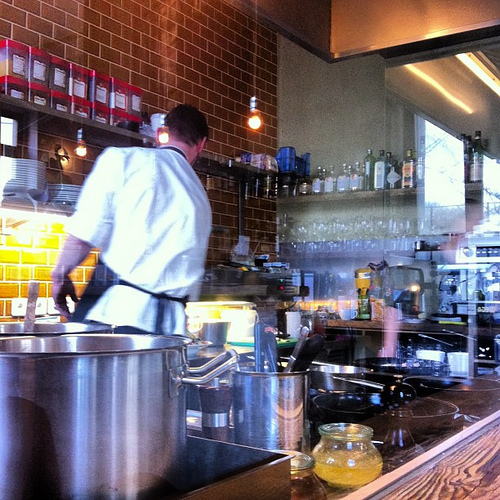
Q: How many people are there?
A: One.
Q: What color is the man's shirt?
A: White.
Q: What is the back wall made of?
A: Brick.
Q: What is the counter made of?
A: Wood.